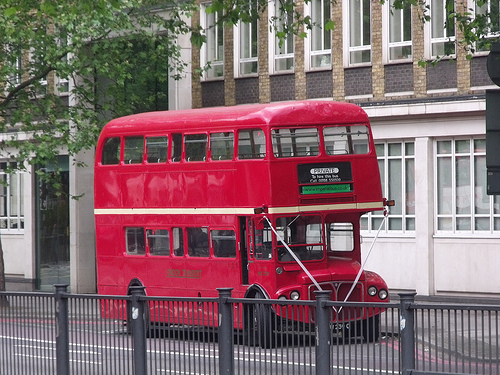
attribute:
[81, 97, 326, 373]
bus — red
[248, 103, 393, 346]
frontal — red, black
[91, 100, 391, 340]
bus — red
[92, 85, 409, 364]
bus — red